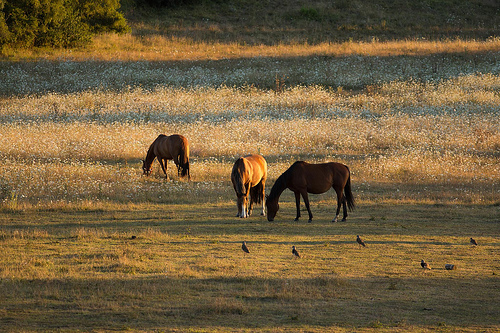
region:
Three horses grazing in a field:
[28, 43, 483, 246]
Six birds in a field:
[237, 232, 489, 289]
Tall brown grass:
[275, 80, 457, 152]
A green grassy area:
[50, 260, 226, 310]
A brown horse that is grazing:
[258, 149, 366, 229]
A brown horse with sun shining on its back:
[218, 148, 268, 220]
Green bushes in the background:
[10, 5, 145, 56]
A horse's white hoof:
[330, 210, 340, 225]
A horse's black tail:
[341, 163, 358, 214]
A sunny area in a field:
[197, 90, 291, 143]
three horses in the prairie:
[119, 121, 369, 229]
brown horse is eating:
[131, 119, 201, 194]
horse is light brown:
[227, 143, 270, 225]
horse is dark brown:
[260, 154, 360, 231]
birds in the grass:
[236, 219, 490, 288]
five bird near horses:
[224, 213, 488, 282]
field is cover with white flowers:
[11, 39, 498, 192]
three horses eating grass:
[122, 114, 368, 230]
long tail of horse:
[344, 162, 356, 213]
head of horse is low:
[131, 144, 157, 181]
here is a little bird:
[236, 235, 251, 258]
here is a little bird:
[288, 243, 304, 260]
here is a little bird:
[348, 232, 370, 252]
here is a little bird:
[413, 255, 435, 277]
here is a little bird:
[466, 232, 481, 252]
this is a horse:
[138, 130, 200, 190]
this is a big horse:
[265, 158, 365, 230]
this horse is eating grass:
[229, 151, 271, 228]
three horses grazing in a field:
[135, 127, 362, 237]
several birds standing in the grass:
[218, 222, 488, 292]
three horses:
[141, 132, 353, 219]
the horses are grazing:
[136, 131, 351, 221]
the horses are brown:
[141, 127, 357, 218]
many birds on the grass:
[123, 235, 480, 272]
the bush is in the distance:
[3, 2, 130, 49]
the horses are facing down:
[138, 133, 358, 221]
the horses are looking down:
[141, 132, 358, 219]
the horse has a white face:
[240, 199, 247, 219]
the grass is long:
[7, 1, 497, 195]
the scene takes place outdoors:
[0, 5, 499, 328]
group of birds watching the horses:
[220, 228, 481, 275]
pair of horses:
[215, 131, 363, 214]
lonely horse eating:
[124, 128, 199, 184]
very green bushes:
[29, 3, 134, 55]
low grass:
[7, 212, 498, 329]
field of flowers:
[12, 22, 496, 201]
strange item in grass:
[435, 254, 462, 283]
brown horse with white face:
[211, 148, 267, 219]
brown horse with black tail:
[270, 150, 365, 220]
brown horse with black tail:
[128, 130, 193, 182]